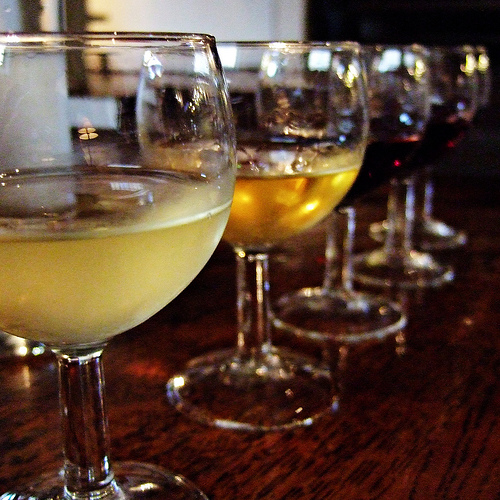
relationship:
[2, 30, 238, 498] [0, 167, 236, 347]
glass for wine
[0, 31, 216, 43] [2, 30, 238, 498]
rim of glass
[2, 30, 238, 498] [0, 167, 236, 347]
glass of wine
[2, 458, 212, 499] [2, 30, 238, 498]
base of glass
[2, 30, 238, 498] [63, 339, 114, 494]
glass has stem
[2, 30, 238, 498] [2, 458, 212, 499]
glass has base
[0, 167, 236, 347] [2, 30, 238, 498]
wine in glass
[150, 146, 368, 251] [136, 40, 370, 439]
wine in glass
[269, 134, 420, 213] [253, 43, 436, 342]
wine in glass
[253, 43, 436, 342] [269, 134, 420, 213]
glass of wine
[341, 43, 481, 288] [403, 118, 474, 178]
glass of wine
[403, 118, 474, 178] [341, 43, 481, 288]
wine in glass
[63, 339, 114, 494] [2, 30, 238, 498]
stem of glass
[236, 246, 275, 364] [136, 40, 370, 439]
stem of glass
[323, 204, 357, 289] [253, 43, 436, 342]
stem of glass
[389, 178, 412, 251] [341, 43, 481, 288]
stem of glass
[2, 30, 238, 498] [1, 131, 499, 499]
glass on table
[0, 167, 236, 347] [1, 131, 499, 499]
wine above table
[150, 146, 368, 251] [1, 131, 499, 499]
wine above table